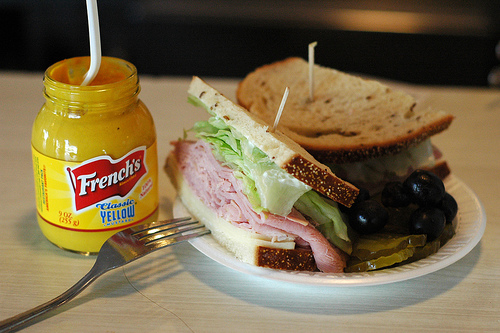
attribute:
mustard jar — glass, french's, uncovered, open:
[29, 50, 167, 259]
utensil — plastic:
[83, 0, 103, 83]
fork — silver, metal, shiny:
[0, 209, 215, 332]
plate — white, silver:
[167, 169, 490, 297]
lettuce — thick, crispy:
[191, 102, 353, 252]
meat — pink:
[169, 134, 344, 274]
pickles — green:
[346, 227, 443, 277]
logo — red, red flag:
[62, 143, 157, 214]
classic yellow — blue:
[96, 197, 141, 226]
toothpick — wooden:
[306, 38, 322, 108]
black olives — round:
[344, 166, 461, 243]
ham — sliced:
[166, 131, 342, 271]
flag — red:
[62, 140, 156, 219]